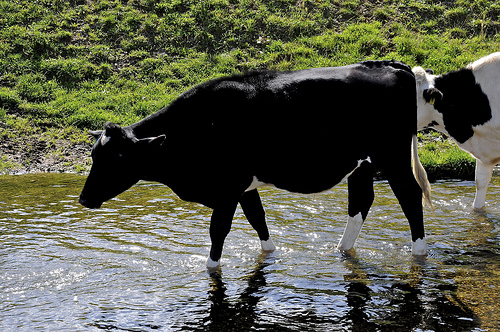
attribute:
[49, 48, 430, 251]
black cow — white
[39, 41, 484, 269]
cow — black 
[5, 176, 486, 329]
water — shallow, clear 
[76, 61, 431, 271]
cow — black, white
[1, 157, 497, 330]
water — green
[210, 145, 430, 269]
markings — white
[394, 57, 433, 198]
tail — down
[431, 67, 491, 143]
spot — black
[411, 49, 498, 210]
cow — black, white